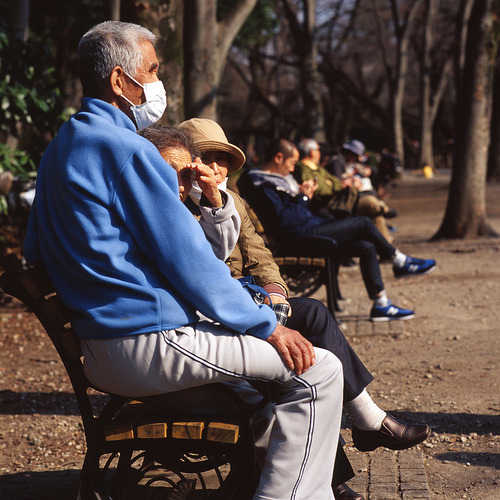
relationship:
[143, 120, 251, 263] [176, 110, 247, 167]
woman wearing hat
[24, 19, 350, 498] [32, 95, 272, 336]
man wearing shirt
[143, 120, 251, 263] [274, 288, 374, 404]
woman wearing pants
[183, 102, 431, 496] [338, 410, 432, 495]
woman wearing shoes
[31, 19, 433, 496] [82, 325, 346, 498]
man wearing pants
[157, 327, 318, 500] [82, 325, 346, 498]
stripe on pants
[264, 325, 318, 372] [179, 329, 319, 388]
man's hand on thigh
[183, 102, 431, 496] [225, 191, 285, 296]
woman wearing jacket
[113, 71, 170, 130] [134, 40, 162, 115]
mask on face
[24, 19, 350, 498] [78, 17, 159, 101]
man has hair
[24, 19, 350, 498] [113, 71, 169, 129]
man has mask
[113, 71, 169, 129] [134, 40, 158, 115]
mask on face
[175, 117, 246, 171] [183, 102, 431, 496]
hat on woman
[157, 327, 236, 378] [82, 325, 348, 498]
stripe on pants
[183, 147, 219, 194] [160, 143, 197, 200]
hand on face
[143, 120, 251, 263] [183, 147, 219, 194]
woman has hand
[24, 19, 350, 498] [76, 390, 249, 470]
man on bench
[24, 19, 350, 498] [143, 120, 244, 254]
man by woman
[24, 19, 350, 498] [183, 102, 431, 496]
man by woman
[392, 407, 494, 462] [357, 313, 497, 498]
shadow on ground